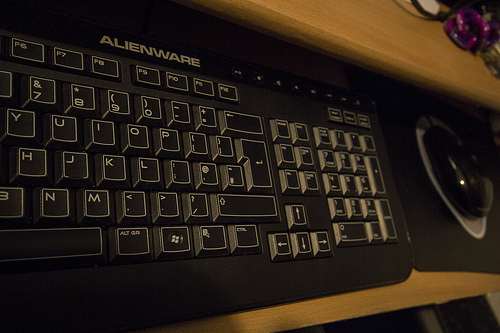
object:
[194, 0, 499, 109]
shelf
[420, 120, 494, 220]
mouse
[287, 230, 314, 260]
arrow keys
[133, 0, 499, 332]
computer table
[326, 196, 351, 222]
numeric keys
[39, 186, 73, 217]
alphabet keys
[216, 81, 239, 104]
function keys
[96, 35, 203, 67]
brand name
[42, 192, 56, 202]
letters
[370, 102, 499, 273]
mousepad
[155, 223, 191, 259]
key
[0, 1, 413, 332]
keyboard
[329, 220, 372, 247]
number keys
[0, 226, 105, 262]
space bar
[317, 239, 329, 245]
arrow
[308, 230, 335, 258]
key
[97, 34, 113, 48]
letters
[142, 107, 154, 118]
number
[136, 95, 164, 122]
key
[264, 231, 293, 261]
key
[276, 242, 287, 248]
arrow